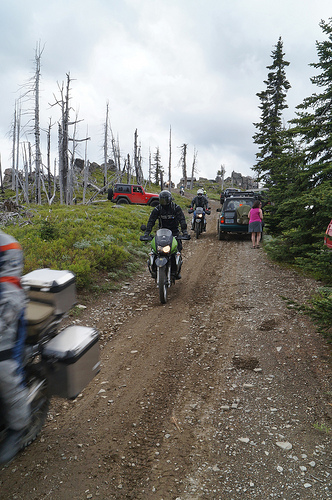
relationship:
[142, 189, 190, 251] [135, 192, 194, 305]
man riding bike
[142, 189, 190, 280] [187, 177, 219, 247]
man riding bike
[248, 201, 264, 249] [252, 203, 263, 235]
woman wears clothes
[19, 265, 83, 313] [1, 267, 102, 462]
container on vehicle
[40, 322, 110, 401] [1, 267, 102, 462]
container on vehicle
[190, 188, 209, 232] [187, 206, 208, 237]
man on bike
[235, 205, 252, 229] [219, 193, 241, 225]
tire on vehicle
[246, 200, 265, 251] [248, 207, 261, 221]
woman wears shirt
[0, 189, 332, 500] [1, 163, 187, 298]
dirt road near grass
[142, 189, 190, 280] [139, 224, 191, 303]
man on bike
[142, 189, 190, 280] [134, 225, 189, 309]
man on bike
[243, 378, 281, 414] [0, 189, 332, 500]
rocks on dirt road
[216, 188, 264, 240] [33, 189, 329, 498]
vehicle on dirt road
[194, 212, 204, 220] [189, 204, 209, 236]
light on bike